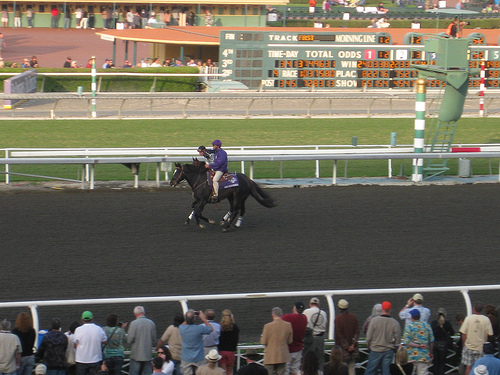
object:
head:
[81, 314, 94, 323]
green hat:
[81, 309, 94, 321]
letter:
[269, 32, 299, 43]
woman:
[155, 346, 174, 374]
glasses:
[157, 351, 164, 354]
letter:
[305, 48, 332, 58]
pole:
[476, 52, 486, 116]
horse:
[169, 156, 278, 233]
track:
[0, 187, 500, 345]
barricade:
[0, 284, 500, 341]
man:
[72, 310, 109, 373]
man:
[259, 307, 293, 375]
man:
[458, 302, 494, 375]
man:
[177, 309, 214, 375]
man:
[364, 300, 402, 375]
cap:
[80, 310, 93, 321]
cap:
[382, 300, 393, 310]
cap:
[412, 293, 424, 301]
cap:
[310, 297, 320, 305]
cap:
[211, 139, 222, 147]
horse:
[169, 161, 272, 233]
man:
[197, 138, 229, 199]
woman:
[218, 309, 240, 374]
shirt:
[192, 363, 224, 375]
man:
[194, 349, 226, 375]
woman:
[101, 314, 129, 369]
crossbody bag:
[101, 325, 123, 353]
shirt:
[402, 320, 437, 364]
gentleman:
[259, 305, 294, 374]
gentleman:
[204, 138, 229, 200]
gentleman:
[364, 300, 402, 374]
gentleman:
[458, 301, 494, 374]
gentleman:
[72, 310, 108, 374]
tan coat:
[258, 317, 293, 364]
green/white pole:
[410, 89, 426, 182]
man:
[402, 309, 436, 375]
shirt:
[432, 319, 455, 341]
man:
[125, 305, 156, 374]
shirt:
[218, 322, 240, 352]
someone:
[400, 309, 437, 375]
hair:
[133, 305, 146, 313]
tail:
[244, 171, 277, 208]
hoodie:
[197, 145, 215, 164]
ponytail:
[227, 310, 237, 327]